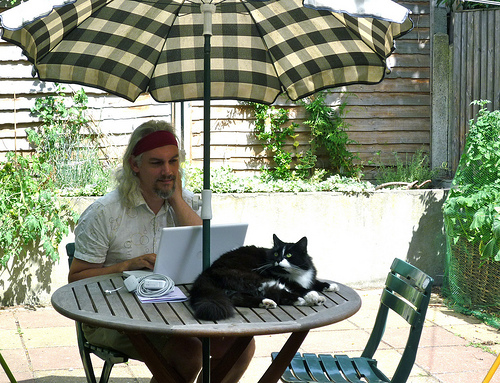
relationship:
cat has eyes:
[187, 232, 339, 319] [271, 252, 296, 257]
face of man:
[143, 142, 179, 201] [68, 119, 253, 381]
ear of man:
[108, 151, 140, 173] [105, 120, 216, 280]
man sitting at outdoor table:
[68, 119, 253, 381] [50, 270, 364, 381]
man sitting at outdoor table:
[68, 119, 253, 381] [50, 271, 359, 380]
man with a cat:
[68, 119, 253, 381] [187, 232, 339, 319]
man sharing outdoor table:
[68, 119, 253, 381] [50, 270, 364, 381]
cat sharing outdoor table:
[187, 232, 339, 319] [50, 270, 364, 381]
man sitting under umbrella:
[67, 120, 255, 383] [0, 1, 410, 359]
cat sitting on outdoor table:
[187, 233, 338, 321] [50, 271, 359, 380]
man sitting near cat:
[68, 119, 253, 381] [187, 232, 339, 319]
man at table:
[67, 120, 255, 383] [52, 259, 363, 336]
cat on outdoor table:
[187, 232, 339, 319] [50, 271, 359, 380]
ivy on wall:
[23, 87, 90, 165] [2, 0, 429, 179]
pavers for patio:
[4, 286, 499, 378] [2, 204, 497, 381]